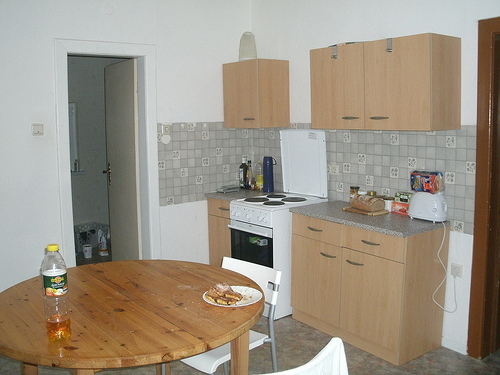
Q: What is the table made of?
A: Wood.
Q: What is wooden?
A: Kitchen table.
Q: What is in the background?
A: Cabinets.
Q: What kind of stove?
A: Electrical.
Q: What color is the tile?
A: Gray.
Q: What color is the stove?
A: White.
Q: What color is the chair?
A: White.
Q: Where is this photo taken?
A: In a kitchen.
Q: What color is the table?
A: Brown.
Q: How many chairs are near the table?
A: Two.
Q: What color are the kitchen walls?
A: White.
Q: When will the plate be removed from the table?
A: When the man or woman comes to the kitchen and gets it off of the table.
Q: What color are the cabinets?
A: Brown.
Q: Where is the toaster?
A: On the counter.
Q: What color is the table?
A: Brown.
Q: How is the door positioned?
A: Open.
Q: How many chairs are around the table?
A: Two.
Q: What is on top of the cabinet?
A: An air freshener.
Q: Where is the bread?
A: On the counter.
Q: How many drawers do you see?
A: Three.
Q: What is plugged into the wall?
A: The toaster.